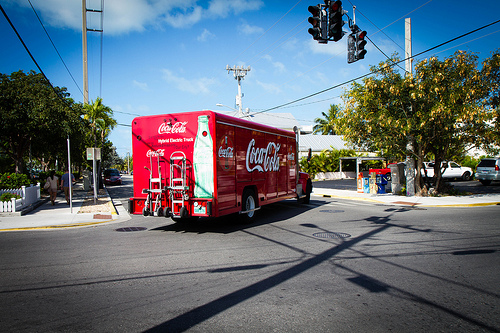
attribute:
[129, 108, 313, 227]
truck — red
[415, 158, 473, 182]
truck — white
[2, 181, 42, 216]
fence — white, picket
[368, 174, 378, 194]
box — yellow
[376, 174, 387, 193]
box — blue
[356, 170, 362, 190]
box — red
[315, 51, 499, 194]
tree — green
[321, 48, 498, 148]
flowers — yellow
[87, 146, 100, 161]
sign — backwards, metal, behind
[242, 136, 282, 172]
letters — white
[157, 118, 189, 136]
letters — white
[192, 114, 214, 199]
bottle — empty, drawing, picture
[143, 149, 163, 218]
dolly — metal, silver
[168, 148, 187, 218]
dolly — metal, silver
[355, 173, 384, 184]
newspapers — sale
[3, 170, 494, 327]
street — black, paved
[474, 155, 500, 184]
truck — white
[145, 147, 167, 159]
logo — white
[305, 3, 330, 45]
traffic light — hanging, black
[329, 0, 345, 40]
traffic light — hanging, black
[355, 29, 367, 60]
traffic light — hanging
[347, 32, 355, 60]
traffic light — hanging, black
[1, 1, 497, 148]
sky — blue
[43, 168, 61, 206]
person — walking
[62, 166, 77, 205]
person — walking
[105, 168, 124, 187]
car — parked, white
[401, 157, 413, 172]
truck — silver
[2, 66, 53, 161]
tree — green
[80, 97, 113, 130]
tree — palm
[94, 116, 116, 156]
tree — palm